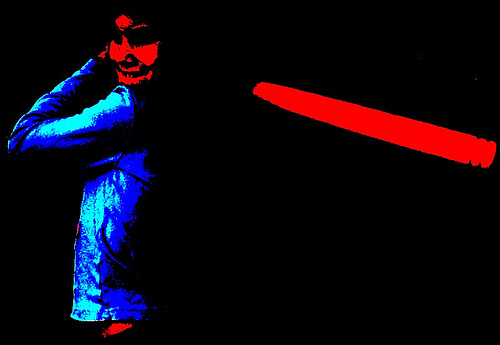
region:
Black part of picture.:
[274, 191, 376, 265]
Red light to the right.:
[260, 73, 440, 158]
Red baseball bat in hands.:
[182, 36, 493, 187]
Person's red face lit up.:
[94, 13, 184, 78]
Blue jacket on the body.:
[52, 101, 147, 299]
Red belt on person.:
[91, 319, 136, 343]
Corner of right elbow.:
[12, 111, 62, 165]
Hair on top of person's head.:
[115, 11, 192, 23]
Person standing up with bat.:
[14, 19, 179, 336]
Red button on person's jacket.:
[70, 208, 95, 246]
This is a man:
[124, 55, 154, 185]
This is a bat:
[287, 89, 493, 205]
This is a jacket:
[92, 214, 120, 248]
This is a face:
[109, 36, 199, 131]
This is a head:
[88, 14, 176, 71]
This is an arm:
[13, 95, 94, 155]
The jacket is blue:
[95, 250, 151, 297]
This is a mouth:
[101, 66, 141, 87]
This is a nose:
[112, 39, 139, 69]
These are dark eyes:
[99, 32, 154, 49]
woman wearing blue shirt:
[5, 5, 166, 339]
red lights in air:
[242, 78, 496, 166]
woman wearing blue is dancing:
[3, 3, 185, 342]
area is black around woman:
[4, 2, 496, 341]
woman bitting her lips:
[4, 8, 179, 339]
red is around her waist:
[4, 7, 172, 340]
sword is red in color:
[245, 77, 496, 175]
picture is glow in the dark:
[4, 3, 495, 343]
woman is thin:
[4, 3, 175, 343]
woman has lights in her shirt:
[3, 0, 178, 340]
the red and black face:
[106, 13, 164, 91]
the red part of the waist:
[91, 311, 156, 336]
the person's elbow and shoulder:
[25, 110, 166, 143]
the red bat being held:
[246, 53, 496, 184]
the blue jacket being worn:
[28, 50, 200, 332]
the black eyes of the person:
[108, 27, 178, 47]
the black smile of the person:
[113, 67, 154, 79]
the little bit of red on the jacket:
[66, 220, 83, 234]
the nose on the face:
[116, 48, 142, 68]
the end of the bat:
[468, 138, 498, 178]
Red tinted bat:
[237, 69, 494, 181]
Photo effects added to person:
[10, 11, 175, 329]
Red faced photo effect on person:
[91, 12, 168, 85]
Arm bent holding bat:
[7, 55, 139, 157]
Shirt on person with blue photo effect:
[8, 56, 160, 324]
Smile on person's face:
[110, 62, 150, 79]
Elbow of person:
[5, 123, 42, 154]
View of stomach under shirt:
[90, 320, 132, 339]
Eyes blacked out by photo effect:
[99, 24, 159, 47]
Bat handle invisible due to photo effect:
[161, 49, 256, 103]